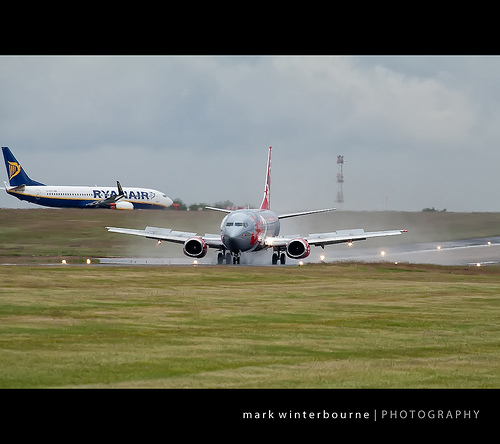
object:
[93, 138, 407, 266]
plane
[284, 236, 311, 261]
engine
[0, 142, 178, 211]
plane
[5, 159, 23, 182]
logo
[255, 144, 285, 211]
white plane's tail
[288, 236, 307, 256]
red propeller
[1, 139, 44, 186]
blue tail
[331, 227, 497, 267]
airport runway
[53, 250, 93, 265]
illuminated lights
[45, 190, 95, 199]
row of windows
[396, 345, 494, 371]
patches of grass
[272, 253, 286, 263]
black wheel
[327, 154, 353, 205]
tower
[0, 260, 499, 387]
field next to runway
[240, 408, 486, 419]
credit at bottom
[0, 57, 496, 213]
sky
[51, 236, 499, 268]
runway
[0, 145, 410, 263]
two planes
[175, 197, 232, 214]
few trees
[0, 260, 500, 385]
some grass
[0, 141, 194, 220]
plane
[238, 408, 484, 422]
white text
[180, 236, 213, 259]
jet engine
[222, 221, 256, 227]
cockpit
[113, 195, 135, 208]
jet engine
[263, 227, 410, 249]
wing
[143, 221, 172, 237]
rudder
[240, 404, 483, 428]
logo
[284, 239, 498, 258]
row of lights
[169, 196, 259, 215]
group of plants